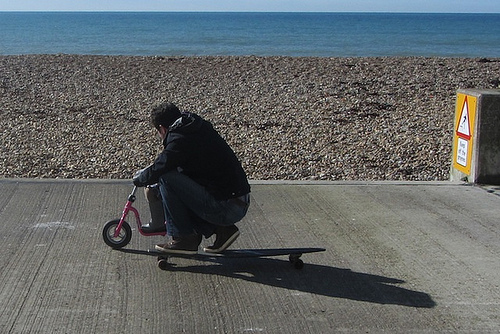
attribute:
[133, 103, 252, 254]
man — kneeling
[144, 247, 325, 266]
skateboard — black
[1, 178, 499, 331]
ground — concrete, cement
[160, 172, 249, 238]
jeans — blue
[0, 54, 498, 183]
beach — pebbled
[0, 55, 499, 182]
pebbles — gray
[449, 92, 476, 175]
sign — yellow, red, black, white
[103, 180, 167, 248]
scooter — pink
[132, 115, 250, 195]
jacket — black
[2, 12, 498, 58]
water — dark blue, still, calm, large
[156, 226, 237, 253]
shoes — brown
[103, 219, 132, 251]
tire — black, small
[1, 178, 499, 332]
concrete — ridged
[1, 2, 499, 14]
sky — clear, blue